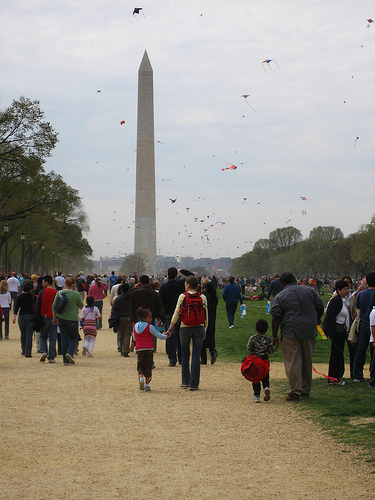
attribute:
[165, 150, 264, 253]
kites — colorful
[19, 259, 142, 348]
people — walking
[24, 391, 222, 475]
walkway — dusty, brown, brow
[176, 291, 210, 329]
backpack — red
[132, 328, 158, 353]
vest — red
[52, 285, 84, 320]
blouse — green